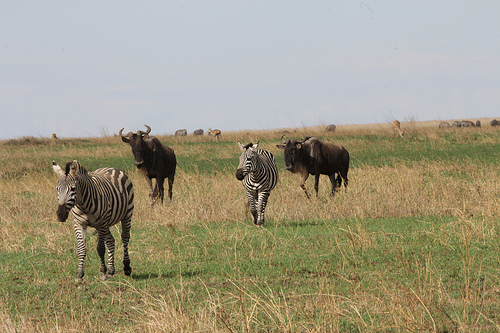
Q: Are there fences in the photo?
A: No, there are no fences.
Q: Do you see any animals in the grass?
A: Yes, there is an animal in the grass.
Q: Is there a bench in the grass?
A: No, there is an animal in the grass.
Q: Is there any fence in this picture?
A: No, there are no fences.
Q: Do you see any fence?
A: No, there are no fences.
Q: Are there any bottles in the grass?
A: No, there is an animal in the grass.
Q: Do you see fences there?
A: No, there are no fences.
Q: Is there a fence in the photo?
A: No, there are no fences.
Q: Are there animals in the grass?
A: Yes, there is an animal in the grass.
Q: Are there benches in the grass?
A: No, there is an animal in the grass.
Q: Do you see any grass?
A: Yes, there is grass.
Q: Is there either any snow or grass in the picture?
A: Yes, there is grass.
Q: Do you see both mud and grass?
A: No, there is grass but no mud.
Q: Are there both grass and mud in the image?
A: No, there is grass but no mud.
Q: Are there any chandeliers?
A: No, there are no chandeliers.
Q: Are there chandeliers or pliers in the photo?
A: No, there are no chandeliers or pliers.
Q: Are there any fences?
A: No, there are no fences.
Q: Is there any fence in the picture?
A: No, there are no fences.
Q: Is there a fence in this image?
A: No, there are no fences.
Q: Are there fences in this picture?
A: No, there are no fences.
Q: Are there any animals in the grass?
A: Yes, there is an animal in the grass.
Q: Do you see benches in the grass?
A: No, there is an animal in the grass.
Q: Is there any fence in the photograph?
A: No, there are no fences.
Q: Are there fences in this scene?
A: No, there are no fences.